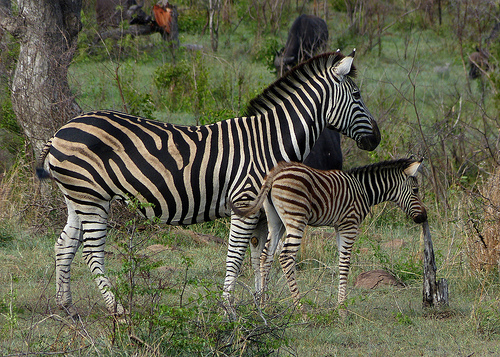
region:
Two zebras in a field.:
[33, 45, 428, 326]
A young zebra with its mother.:
[233, 155, 428, 330]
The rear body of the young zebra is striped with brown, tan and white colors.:
[232, 157, 352, 320]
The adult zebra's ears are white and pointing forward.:
[330, 40, 356, 76]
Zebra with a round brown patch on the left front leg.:
[246, 232, 261, 249]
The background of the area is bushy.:
[2, 2, 262, 102]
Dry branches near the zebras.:
[434, 4, 498, 351]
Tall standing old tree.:
[3, 3, 74, 233]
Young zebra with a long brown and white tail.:
[226, 165, 276, 220]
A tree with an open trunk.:
[147, 1, 187, 63]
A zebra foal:
[285, 179, 375, 202]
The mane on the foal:
[377, 163, 402, 165]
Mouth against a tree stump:
[418, 218, 427, 223]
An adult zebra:
[100, 133, 260, 178]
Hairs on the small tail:
[233, 208, 238, 212]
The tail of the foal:
[262, 186, 267, 190]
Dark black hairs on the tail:
[38, 170, 45, 176]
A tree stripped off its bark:
[156, 9, 169, 21]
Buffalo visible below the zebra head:
[319, 141, 337, 163]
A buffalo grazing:
[278, 58, 290, 68]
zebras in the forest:
[32, 48, 432, 317]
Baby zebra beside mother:
[228, 159, 427, 304]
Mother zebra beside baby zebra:
[38, 43, 379, 325]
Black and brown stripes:
[263, 159, 335, 233]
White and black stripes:
[219, 53, 369, 189]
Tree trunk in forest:
[8, 0, 80, 155]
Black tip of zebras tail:
[33, 160, 50, 182]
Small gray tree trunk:
[424, 216, 450, 305]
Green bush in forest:
[103, 198, 289, 351]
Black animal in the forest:
[275, 11, 330, 70]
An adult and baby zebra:
[5, 43, 432, 323]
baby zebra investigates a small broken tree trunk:
[396, 157, 450, 315]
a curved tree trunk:
[6, 5, 87, 222]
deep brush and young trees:
[69, 38, 498, 127]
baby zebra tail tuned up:
[226, 164, 300, 225]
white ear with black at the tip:
[326, 44, 362, 76]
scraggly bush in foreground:
[107, 227, 288, 355]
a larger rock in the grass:
[347, 257, 409, 292]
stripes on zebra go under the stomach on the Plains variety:
[50, 56, 375, 241]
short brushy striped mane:
[224, 47, 334, 122]